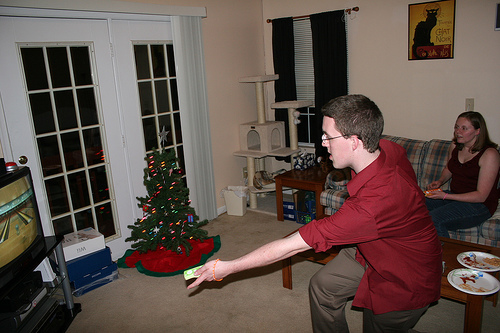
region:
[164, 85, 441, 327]
boy playing a video game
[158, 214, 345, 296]
boy holding a game remte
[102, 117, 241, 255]
a small christmas tree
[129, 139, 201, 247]
the tree has lights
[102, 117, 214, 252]
the lights are multi colored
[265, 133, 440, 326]
the boy`s shirt is maroon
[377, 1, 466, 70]
picture on the wall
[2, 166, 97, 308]
the tv is on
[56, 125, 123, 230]
the window is reflecting the lights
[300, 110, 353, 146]
boy is wearing glasses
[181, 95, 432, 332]
a boy playing wii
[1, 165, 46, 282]
a black crt television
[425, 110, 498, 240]
woman sitting on a couch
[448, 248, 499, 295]
two plates on a table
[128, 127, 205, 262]
a small christmas tree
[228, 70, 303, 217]
a cat tree in the corner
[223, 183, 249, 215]
a small white trashcan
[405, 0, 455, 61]
a yellow red and black poster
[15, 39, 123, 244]
windows on a door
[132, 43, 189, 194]
windows on a door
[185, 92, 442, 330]
Man playing video games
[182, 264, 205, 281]
Video game controller in the man's left hand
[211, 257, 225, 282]
Band on the man's wrist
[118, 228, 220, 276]
Blanket on the floor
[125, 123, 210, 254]
Christmas tree on the blanket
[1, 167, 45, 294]
TV on a stand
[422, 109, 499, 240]
Woman sitting on a couch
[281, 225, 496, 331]
Coffee table in front of the couch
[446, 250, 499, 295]
Paper plates on the coffee table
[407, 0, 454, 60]
Picture on the wall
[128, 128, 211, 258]
a small Christmas tree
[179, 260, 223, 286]
a small white Wii remote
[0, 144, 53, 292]
a black analogue TV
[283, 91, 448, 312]
a man wearing a red shirt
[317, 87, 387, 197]
a man wearing glasses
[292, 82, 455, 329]
a man wearing brown pants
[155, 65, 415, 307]
a man holding a Wii remote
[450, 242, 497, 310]
two paper plates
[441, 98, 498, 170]
a woman with long hair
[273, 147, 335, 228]
a wooden end table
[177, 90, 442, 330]
A man in a red shirt.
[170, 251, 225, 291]
A hand holding a controller.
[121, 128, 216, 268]
A small Christmas tree.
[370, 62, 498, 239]
A woman sitting on a couch.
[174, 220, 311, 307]
a left human arm.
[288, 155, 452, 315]
a red shirt.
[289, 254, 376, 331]
a pair of brown pants.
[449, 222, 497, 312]
two paper plates.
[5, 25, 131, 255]
a glass door.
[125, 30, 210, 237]
a right glass door.